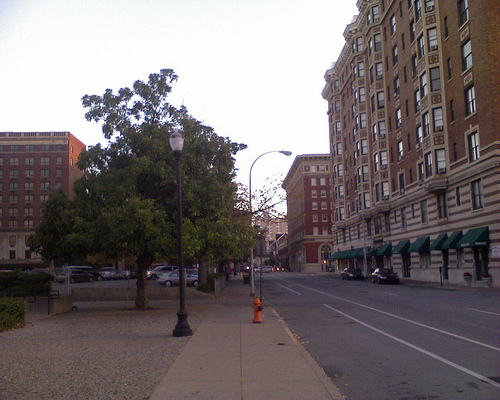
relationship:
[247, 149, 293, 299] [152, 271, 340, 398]
street light on sidewalk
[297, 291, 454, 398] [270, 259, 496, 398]
line in middle of road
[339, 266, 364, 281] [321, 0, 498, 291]
car parking in front a building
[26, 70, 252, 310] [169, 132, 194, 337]
tree behind a street light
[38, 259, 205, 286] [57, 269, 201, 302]
cars parked in a parking lot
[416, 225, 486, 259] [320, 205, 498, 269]
awnings on building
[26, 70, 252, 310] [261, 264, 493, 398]
tree in street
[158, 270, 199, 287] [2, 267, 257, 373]
car in parking lot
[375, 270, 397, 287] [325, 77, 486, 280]
cars parked next to building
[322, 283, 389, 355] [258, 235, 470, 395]
tarmacked road in a street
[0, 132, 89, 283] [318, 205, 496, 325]
building on left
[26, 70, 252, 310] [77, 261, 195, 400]
tree on side of street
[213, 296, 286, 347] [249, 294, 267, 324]
orange and black fire hydrant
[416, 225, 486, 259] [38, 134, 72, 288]
awnings on building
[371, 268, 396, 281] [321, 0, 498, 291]
car parallel parked outside building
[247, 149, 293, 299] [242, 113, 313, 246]
street light with curve at top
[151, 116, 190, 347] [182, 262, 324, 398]
post along sidewalk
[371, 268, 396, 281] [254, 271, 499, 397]
car parked along street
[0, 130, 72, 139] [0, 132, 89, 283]
writing on top side of building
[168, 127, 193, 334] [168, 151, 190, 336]
lamp on pole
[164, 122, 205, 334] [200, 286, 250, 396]
light pole on sidewalk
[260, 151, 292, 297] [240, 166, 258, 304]
street lamp on pole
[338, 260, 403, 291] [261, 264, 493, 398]
two cars parked on side of street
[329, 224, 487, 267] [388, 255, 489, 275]
shades over windows